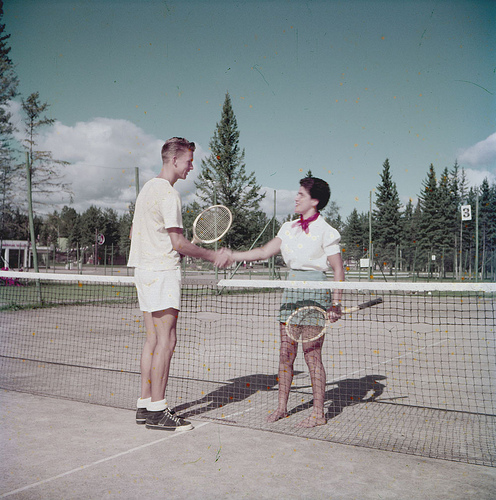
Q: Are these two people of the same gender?
A: No, they are both male and female.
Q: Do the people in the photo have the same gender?
A: No, they are both male and female.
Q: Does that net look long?
A: Yes, the net is long.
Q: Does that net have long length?
A: Yes, the net is long.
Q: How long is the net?
A: The net is long.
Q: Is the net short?
A: No, the net is long.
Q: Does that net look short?
A: No, the net is long.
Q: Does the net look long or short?
A: The net is long.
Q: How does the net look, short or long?
A: The net is long.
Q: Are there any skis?
A: No, there are no skis.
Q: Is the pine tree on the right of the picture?
A: Yes, the pine tree is on the right of the image.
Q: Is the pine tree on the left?
A: No, the pine tree is on the right of the image.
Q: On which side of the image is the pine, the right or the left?
A: The pine is on the right of the image.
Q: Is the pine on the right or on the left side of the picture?
A: The pine is on the right of the image.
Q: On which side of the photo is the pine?
A: The pine is on the right of the image.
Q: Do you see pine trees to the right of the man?
A: Yes, there is a pine tree to the right of the man.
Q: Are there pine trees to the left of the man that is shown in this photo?
A: No, the pine tree is to the right of the man.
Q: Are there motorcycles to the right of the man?
A: No, there is a pine tree to the right of the man.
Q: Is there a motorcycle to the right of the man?
A: No, there is a pine tree to the right of the man.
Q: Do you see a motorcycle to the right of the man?
A: No, there is a pine tree to the right of the man.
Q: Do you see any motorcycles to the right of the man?
A: No, there is a pine tree to the right of the man.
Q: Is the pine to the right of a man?
A: Yes, the pine is to the right of a man.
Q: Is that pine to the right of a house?
A: No, the pine is to the right of a man.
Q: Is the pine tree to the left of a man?
A: No, the pine tree is to the right of a man.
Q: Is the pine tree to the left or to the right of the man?
A: The pine tree is to the right of the man.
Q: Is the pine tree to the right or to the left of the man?
A: The pine tree is to the right of the man.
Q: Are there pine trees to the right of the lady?
A: Yes, there is a pine tree to the right of the lady.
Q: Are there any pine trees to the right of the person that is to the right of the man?
A: Yes, there is a pine tree to the right of the lady.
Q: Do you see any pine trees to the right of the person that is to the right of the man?
A: Yes, there is a pine tree to the right of the lady.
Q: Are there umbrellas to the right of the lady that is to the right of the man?
A: No, there is a pine tree to the right of the lady.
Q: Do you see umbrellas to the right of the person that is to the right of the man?
A: No, there is a pine tree to the right of the lady.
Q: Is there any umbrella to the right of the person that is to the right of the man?
A: No, there is a pine tree to the right of the lady.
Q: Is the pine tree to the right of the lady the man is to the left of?
A: Yes, the pine tree is to the right of the lady.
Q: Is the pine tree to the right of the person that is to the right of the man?
A: Yes, the pine tree is to the right of the lady.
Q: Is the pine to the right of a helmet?
A: No, the pine is to the right of the lady.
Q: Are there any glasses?
A: No, there are no glasses.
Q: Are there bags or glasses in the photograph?
A: No, there are no glasses or bags.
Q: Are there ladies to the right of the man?
A: Yes, there is a lady to the right of the man.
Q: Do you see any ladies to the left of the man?
A: No, the lady is to the right of the man.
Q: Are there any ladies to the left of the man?
A: No, the lady is to the right of the man.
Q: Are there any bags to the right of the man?
A: No, there is a lady to the right of the man.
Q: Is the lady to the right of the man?
A: Yes, the lady is to the right of the man.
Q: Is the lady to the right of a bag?
A: No, the lady is to the right of the man.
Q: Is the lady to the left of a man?
A: No, the lady is to the right of a man.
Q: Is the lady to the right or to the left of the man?
A: The lady is to the right of the man.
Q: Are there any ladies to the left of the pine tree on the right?
A: Yes, there is a lady to the left of the pine.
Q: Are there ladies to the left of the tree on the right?
A: Yes, there is a lady to the left of the pine.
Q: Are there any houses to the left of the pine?
A: No, there is a lady to the left of the pine.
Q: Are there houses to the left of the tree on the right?
A: No, there is a lady to the left of the pine.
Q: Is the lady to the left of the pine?
A: Yes, the lady is to the left of the pine.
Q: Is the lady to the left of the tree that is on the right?
A: Yes, the lady is to the left of the pine.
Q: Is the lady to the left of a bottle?
A: No, the lady is to the left of the pine.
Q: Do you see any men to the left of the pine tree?
A: Yes, there is a man to the left of the pine tree.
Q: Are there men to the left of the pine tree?
A: Yes, there is a man to the left of the pine tree.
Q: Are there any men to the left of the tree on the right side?
A: Yes, there is a man to the left of the pine tree.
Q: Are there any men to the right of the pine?
A: No, the man is to the left of the pine.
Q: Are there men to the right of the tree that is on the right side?
A: No, the man is to the left of the pine.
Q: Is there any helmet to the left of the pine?
A: No, there is a man to the left of the pine.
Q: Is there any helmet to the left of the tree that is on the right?
A: No, there is a man to the left of the pine.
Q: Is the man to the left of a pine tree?
A: Yes, the man is to the left of a pine tree.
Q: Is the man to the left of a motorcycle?
A: No, the man is to the left of a pine tree.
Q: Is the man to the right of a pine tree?
A: No, the man is to the left of a pine tree.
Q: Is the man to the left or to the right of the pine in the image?
A: The man is to the left of the pine.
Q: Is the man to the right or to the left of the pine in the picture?
A: The man is to the left of the pine.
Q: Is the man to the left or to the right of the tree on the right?
A: The man is to the left of the pine.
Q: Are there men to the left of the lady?
A: Yes, there is a man to the left of the lady.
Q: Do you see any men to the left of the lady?
A: Yes, there is a man to the left of the lady.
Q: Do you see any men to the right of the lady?
A: No, the man is to the left of the lady.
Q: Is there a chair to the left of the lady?
A: No, there is a man to the left of the lady.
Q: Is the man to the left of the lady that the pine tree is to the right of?
A: Yes, the man is to the left of the lady.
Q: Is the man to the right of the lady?
A: No, the man is to the left of the lady.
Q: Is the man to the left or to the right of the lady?
A: The man is to the left of the lady.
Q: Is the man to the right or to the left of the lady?
A: The man is to the left of the lady.